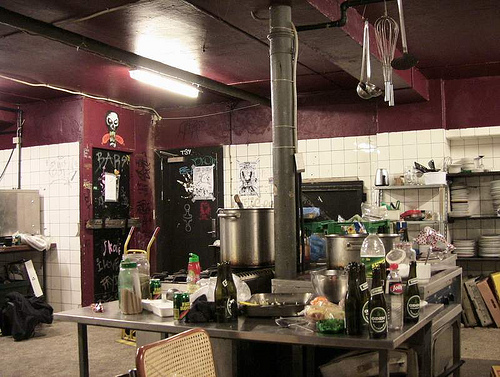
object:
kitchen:
[0, 0, 500, 377]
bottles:
[343, 263, 364, 338]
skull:
[100, 108, 128, 149]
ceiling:
[0, 0, 500, 105]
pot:
[217, 207, 280, 269]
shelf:
[448, 213, 499, 222]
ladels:
[354, 14, 385, 101]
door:
[153, 141, 226, 284]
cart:
[113, 324, 160, 348]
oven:
[418, 267, 466, 333]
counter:
[48, 294, 448, 377]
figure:
[121, 155, 128, 168]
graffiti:
[93, 151, 129, 210]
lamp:
[124, 68, 206, 101]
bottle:
[186, 252, 202, 292]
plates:
[451, 237, 474, 242]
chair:
[130, 323, 225, 377]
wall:
[0, 138, 84, 321]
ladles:
[352, 22, 382, 103]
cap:
[390, 263, 399, 270]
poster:
[190, 165, 216, 202]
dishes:
[447, 163, 462, 174]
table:
[49, 300, 445, 377]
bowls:
[452, 239, 475, 242]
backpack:
[0, 290, 57, 343]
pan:
[243, 291, 313, 317]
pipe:
[269, 6, 298, 283]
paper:
[104, 171, 119, 203]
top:
[188, 252, 201, 264]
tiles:
[57, 155, 69, 171]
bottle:
[366, 268, 389, 341]